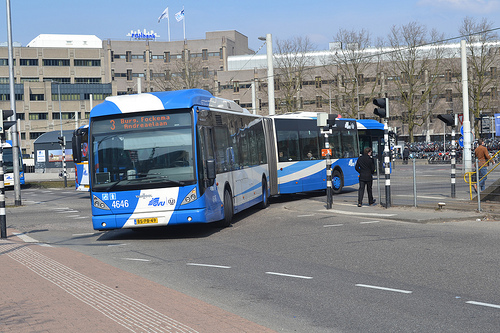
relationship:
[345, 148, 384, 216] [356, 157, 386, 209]
person wearing clothes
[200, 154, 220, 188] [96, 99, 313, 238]
mirror of bus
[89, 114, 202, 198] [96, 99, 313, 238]
screen of bus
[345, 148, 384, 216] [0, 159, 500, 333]
man walking road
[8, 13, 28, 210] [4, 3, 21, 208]
section of pole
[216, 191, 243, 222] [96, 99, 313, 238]
wheel of bus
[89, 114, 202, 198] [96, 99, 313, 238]
window of bus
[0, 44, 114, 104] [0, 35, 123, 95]
section of building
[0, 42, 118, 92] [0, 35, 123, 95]
part of building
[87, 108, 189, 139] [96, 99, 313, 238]
destination on bus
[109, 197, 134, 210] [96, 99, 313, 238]
number on bus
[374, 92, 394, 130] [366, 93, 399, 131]
standing traffic light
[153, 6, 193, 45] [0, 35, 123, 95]
flags on building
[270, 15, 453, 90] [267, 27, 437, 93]
zero tree leaves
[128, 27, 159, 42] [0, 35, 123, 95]
sign top building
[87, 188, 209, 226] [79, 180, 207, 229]
blue white striped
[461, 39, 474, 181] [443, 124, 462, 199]
white stripes poles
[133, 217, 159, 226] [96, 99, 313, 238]
numberplate on bus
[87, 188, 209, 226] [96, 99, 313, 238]
blue bus turning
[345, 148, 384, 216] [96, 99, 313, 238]
person walking bus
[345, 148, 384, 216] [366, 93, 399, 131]
person next light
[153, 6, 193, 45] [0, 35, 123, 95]
flags top building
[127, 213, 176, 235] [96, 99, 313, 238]
numberplate of bus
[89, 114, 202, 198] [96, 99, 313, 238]
front window bus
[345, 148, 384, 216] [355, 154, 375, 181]
man wearing clothes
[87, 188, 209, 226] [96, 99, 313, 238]
blue white bus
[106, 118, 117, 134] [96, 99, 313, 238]
number on bus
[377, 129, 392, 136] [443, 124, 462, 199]
black white poles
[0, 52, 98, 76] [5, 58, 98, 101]
lots of windows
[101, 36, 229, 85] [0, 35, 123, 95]
front of building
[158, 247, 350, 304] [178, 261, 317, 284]
road white stripes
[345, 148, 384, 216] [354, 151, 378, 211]
man wearing suit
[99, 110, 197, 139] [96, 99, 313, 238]
digital display bus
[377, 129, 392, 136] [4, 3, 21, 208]
black white pole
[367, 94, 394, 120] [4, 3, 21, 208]
traffic striped pole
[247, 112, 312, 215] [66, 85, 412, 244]
flexible bus turn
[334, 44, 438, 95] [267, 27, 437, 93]
tree no leaves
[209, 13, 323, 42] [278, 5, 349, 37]
patch blue sky